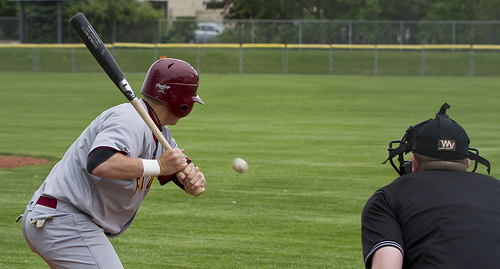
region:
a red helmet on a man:
[136, 50, 210, 123]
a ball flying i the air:
[228, 153, 253, 175]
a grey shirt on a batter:
[35, 94, 182, 231]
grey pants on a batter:
[13, 195, 133, 268]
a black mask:
[374, 108, 494, 178]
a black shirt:
[344, 165, 495, 259]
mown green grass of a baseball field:
[1, 72, 498, 265]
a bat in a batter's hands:
[67, 10, 202, 191]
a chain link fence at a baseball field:
[0, 17, 497, 75]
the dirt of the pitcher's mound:
[0, 146, 59, 175]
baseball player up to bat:
[15, 6, 214, 267]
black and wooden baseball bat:
[61, 8, 201, 200]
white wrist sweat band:
[133, 146, 169, 192]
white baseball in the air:
[226, 148, 253, 190]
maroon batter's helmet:
[138, 54, 208, 124]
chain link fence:
[210, 11, 499, 87]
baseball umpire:
[348, 96, 498, 267]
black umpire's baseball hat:
[372, 93, 487, 175]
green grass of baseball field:
[262, 88, 362, 261]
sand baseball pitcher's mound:
[3, 146, 58, 173]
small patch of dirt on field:
[2, 154, 49, 167]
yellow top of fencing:
[2, 44, 498, 49]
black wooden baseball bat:
[74, 14, 202, 194]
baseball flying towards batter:
[226, 154, 249, 172]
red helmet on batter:
[140, 56, 200, 108]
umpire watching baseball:
[355, 112, 492, 267]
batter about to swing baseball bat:
[17, 14, 194, 266]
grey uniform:
[32, 87, 164, 261]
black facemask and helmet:
[381, 112, 471, 175]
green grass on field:
[7, 72, 484, 266]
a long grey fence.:
[141, 12, 485, 54]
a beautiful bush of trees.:
[11, 5, 177, 24]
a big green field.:
[249, 73, 379, 163]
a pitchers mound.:
[0, 135, 45, 180]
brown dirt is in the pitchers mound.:
[0, 151, 42, 172]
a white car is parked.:
[178, 17, 230, 37]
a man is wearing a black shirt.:
[361, 176, 494, 264]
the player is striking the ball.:
[67, 11, 171, 190]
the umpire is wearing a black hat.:
[396, 96, 474, 171]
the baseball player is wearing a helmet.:
[137, 54, 207, 114]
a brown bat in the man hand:
[124, 91, 173, 149]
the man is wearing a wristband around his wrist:
[144, 153, 158, 175]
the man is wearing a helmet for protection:
[146, 47, 198, 108]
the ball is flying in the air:
[227, 146, 247, 197]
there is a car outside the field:
[169, 18, 236, 43]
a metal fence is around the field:
[284, 43, 359, 76]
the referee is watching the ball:
[363, 122, 499, 260]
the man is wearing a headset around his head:
[391, 124, 413, 173]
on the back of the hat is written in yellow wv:
[441, 138, 459, 150]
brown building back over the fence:
[178, 1, 203, 18]